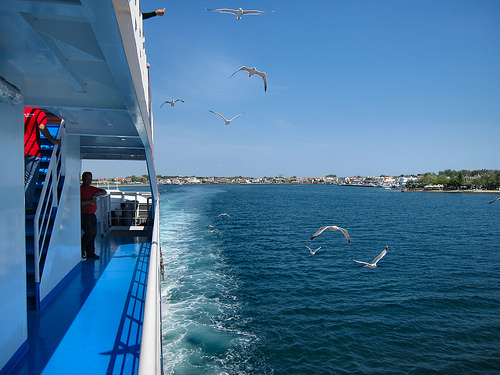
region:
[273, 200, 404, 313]
the birds are flying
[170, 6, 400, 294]
Seagulls flying mid air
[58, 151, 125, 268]
Man standing on boat deck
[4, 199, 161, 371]
Blue boat deck floor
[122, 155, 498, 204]
City coast line in background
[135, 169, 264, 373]
White wave from boat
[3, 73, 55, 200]
Man walking up the steps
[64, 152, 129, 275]
Man standing on deck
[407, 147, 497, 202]
Green trees on coastline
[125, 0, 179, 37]
Man sticking hand off balcony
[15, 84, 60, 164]
Man has a red shirt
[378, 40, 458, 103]
part of the sky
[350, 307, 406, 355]
part of a water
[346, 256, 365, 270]
edge of a wing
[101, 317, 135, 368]
part of a shade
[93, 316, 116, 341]
part of a floor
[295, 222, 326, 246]
edge of a wing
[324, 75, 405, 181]
part of the sky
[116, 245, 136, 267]
part of a shade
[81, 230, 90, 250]
part of a trouser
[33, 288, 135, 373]
blue narrow pathway floor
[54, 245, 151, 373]
blue narrow pathway floor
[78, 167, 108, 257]
man standing along the pathway